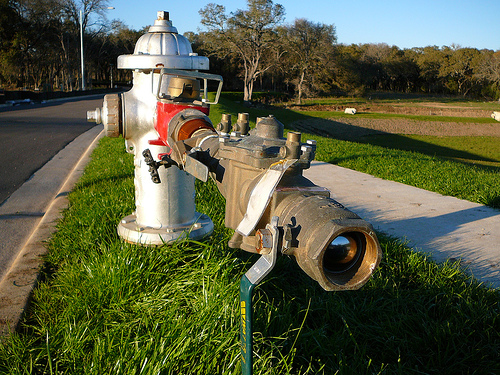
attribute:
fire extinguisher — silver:
[210, 154, 323, 293]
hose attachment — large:
[156, 134, 223, 183]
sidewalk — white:
[347, 179, 368, 197]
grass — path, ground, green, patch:
[370, 156, 423, 177]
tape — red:
[161, 105, 185, 115]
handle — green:
[220, 273, 263, 370]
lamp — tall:
[66, 1, 90, 86]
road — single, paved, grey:
[53, 106, 75, 116]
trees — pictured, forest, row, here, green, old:
[247, 42, 330, 96]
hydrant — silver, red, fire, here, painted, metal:
[117, 40, 197, 75]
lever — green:
[225, 273, 275, 299]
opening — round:
[319, 242, 365, 278]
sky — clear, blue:
[346, 5, 371, 13]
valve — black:
[150, 147, 166, 183]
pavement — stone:
[369, 179, 409, 216]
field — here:
[461, 139, 475, 147]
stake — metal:
[249, 256, 271, 293]